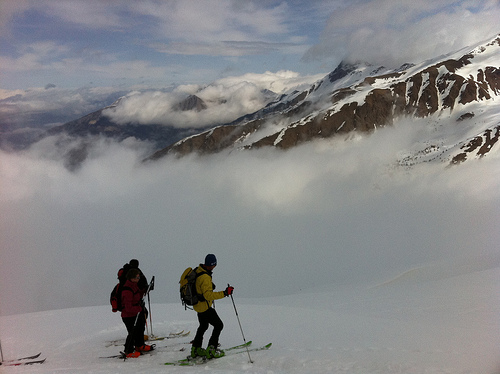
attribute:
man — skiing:
[172, 250, 261, 367]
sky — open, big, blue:
[3, 3, 479, 151]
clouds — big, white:
[7, 145, 499, 289]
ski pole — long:
[226, 286, 260, 366]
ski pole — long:
[143, 283, 155, 344]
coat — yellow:
[179, 270, 230, 314]